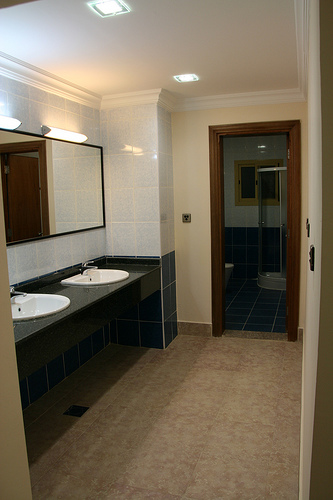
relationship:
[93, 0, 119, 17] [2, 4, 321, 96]
light on ceiling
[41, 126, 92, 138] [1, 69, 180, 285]
light on wall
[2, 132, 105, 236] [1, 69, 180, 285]
mirror on wall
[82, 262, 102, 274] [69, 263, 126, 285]
faucet over sink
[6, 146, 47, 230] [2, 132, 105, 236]
door reflection on mirror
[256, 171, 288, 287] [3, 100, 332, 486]
shower in bathroom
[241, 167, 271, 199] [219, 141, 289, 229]
window on wall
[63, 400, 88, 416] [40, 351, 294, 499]
drain on floor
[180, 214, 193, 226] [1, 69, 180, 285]
plug on wall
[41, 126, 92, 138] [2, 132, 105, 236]
light above mirror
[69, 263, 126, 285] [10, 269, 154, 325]
sink on counter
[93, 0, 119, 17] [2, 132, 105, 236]
light above mirror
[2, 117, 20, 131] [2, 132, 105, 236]
light above mirror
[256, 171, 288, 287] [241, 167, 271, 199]
shower next to window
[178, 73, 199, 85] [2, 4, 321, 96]
light on ceiling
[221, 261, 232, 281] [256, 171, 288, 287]
toilet in front of shower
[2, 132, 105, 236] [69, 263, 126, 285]
mirror above sink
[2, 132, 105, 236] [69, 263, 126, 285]
mirror hanging over sink